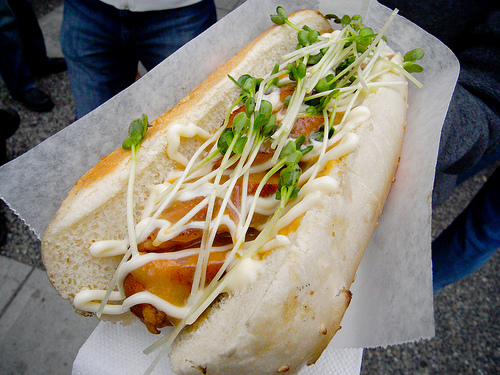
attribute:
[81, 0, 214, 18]
shirt — white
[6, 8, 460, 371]
sheet — white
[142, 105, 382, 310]
bread — textured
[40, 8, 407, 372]
bun — toasted, hot dog, white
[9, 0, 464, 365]
paper — wax, white, flimsy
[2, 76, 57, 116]
shoe — black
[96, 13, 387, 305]
hot dog — cooked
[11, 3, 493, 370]
walkway — cement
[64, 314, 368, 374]
paper towel — thin, meshed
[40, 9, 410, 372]
hotdog — white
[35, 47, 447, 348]
bun — yellow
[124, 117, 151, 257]
vegetable — green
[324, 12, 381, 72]
sprouts — white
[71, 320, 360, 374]
towel — white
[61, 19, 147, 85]
legs — human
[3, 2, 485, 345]
wrapper — white, paper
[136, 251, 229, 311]
cheese — melted, orange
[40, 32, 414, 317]
food — paper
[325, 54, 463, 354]
holder — white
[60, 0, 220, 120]
jeans — blue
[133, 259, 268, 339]
topping — yellow